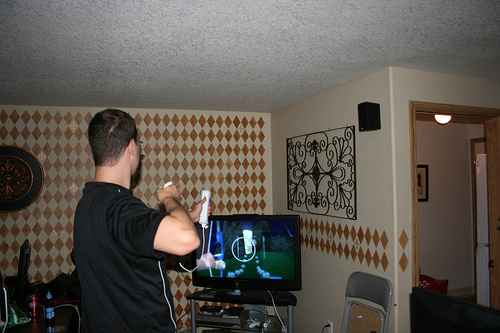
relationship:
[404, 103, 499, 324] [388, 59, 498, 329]
wooden sill on doorway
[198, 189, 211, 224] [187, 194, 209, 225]
controller on hand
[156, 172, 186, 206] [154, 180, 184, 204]
remote on hand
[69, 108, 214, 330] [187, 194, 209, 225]
man has hand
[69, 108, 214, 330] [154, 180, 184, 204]
man has hand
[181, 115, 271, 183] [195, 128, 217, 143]
wall has triangles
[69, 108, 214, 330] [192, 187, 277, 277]
man playing video game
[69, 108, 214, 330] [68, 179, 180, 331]
man wears shirt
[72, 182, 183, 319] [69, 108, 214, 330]
shirt on a man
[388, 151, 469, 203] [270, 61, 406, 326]
picture on wall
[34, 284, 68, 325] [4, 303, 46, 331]
bottle on table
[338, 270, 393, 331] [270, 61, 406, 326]
chair leaning on wall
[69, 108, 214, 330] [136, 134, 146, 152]
man wears glasses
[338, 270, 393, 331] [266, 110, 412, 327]
chair against wall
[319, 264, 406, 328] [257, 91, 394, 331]
chair against wall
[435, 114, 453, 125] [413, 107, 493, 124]
fixture on ceiling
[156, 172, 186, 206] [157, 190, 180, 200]
remote in hand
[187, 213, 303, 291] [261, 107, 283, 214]
television in corner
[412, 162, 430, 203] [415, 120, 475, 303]
picture on wall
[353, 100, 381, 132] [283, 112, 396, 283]
speaker on wall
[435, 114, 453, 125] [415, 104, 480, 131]
fixture on ceiling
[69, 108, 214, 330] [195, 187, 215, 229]
man holds remote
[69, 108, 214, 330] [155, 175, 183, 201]
man holds remote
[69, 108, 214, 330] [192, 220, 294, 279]
man playing video game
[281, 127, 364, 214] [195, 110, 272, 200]
decoration on wall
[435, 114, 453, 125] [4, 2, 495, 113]
fixture on ceiling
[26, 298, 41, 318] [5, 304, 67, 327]
can on table